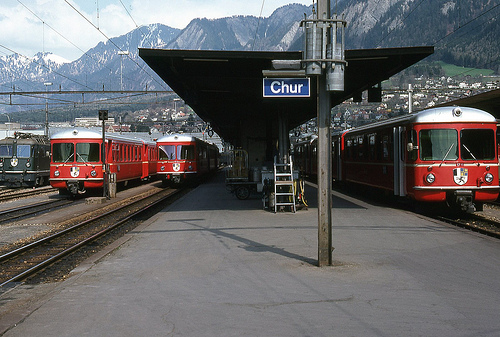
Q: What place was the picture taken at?
A: It was taken at the station.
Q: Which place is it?
A: It is a station.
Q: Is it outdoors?
A: Yes, it is outdoors.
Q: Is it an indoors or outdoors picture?
A: It is outdoors.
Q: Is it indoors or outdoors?
A: It is outdoors.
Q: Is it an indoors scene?
A: No, it is outdoors.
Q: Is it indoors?
A: No, it is outdoors.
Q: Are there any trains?
A: Yes, there is a train.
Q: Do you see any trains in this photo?
A: Yes, there is a train.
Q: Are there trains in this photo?
A: Yes, there is a train.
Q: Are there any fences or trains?
A: Yes, there is a train.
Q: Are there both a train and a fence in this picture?
A: No, there is a train but no fences.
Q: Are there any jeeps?
A: No, there are no jeeps.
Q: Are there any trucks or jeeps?
A: No, there are no jeeps or trucks.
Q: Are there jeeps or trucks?
A: No, there are no jeeps or trucks.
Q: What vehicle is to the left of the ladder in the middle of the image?
A: The vehicle is a train.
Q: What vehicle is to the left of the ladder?
A: The vehicle is a train.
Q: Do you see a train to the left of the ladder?
A: Yes, there is a train to the left of the ladder.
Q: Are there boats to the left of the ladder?
A: No, there is a train to the left of the ladder.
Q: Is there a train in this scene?
A: Yes, there are trains.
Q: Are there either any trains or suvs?
A: Yes, there are trains.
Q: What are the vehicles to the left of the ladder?
A: The vehicles are trains.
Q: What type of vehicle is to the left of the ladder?
A: The vehicles are trains.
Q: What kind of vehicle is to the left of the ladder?
A: The vehicles are trains.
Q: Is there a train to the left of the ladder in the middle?
A: Yes, there are trains to the left of the ladder.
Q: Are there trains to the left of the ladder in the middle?
A: Yes, there are trains to the left of the ladder.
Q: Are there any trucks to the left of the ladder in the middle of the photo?
A: No, there are trains to the left of the ladder.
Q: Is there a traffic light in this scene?
A: No, there are no traffic lights.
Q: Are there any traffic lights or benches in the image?
A: No, there are no traffic lights or benches.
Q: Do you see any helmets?
A: No, there are no helmets.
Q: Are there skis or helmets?
A: No, there are no helmets or skis.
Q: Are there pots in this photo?
A: No, there are no pots.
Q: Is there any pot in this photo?
A: No, there are no pots.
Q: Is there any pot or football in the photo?
A: No, there are no pots or footballs.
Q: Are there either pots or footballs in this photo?
A: No, there are no pots or footballs.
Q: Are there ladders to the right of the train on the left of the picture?
A: Yes, there is a ladder to the right of the train.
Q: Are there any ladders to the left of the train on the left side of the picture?
A: No, the ladder is to the right of the train.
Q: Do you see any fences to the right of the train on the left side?
A: No, there is a ladder to the right of the train.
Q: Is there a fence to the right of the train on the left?
A: No, there is a ladder to the right of the train.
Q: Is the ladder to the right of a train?
A: Yes, the ladder is to the right of a train.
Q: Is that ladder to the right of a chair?
A: No, the ladder is to the right of a train.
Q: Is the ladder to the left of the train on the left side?
A: No, the ladder is to the right of the train.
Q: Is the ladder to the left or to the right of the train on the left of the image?
A: The ladder is to the right of the train.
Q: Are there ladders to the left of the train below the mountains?
A: Yes, there is a ladder to the left of the train.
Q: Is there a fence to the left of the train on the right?
A: No, there is a ladder to the left of the train.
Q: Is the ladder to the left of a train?
A: Yes, the ladder is to the left of a train.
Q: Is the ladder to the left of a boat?
A: No, the ladder is to the left of a train.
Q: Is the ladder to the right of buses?
A: No, the ladder is to the right of the trains.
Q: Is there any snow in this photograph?
A: Yes, there is snow.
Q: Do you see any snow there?
A: Yes, there is snow.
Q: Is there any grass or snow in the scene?
A: Yes, there is snow.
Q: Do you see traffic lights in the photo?
A: No, there are no traffic lights.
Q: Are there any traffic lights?
A: No, there are no traffic lights.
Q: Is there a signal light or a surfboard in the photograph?
A: No, there are no traffic lights or surfboards.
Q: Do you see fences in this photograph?
A: No, there are no fences.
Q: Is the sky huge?
A: Yes, the sky is huge.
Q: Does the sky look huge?
A: Yes, the sky is huge.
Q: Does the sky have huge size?
A: Yes, the sky is huge.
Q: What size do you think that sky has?
A: The sky has huge size.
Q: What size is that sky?
A: The sky is huge.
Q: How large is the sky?
A: The sky is huge.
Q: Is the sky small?
A: No, the sky is huge.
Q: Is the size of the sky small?
A: No, the sky is huge.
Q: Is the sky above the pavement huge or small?
A: The sky is huge.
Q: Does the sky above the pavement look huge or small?
A: The sky is huge.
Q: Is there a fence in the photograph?
A: No, there are no fences.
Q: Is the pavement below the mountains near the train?
A: Yes, the pavement is below the mountains.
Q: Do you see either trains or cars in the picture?
A: Yes, there is a train.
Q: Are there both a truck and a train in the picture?
A: No, there is a train but no trucks.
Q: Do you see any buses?
A: No, there are no buses.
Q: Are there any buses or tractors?
A: No, there are no buses or tractors.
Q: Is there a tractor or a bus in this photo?
A: No, there are no buses or tractors.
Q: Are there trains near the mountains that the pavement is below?
A: Yes, there is a train near the mountains.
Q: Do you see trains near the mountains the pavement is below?
A: Yes, there is a train near the mountains.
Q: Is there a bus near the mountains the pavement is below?
A: No, there is a train near the mountains.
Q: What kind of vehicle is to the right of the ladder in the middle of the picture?
A: The vehicle is a train.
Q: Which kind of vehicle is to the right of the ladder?
A: The vehicle is a train.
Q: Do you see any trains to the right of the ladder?
A: Yes, there is a train to the right of the ladder.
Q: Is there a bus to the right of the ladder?
A: No, there is a train to the right of the ladder.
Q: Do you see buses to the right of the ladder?
A: No, there is a train to the right of the ladder.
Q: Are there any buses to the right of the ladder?
A: No, there is a train to the right of the ladder.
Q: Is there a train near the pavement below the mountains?
A: Yes, there is a train near the pavement.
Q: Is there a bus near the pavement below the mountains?
A: No, there is a train near the pavement.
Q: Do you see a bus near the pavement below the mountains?
A: No, there is a train near the pavement.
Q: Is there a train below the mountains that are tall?
A: Yes, there is a train below the mountains.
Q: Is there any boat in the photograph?
A: No, there are no boats.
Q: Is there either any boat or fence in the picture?
A: No, there are no boats or fences.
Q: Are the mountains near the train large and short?
A: No, the mountains are large but tall.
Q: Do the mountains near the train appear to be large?
A: Yes, the mountains are large.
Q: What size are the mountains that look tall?
A: The mountains are large.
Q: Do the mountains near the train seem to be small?
A: No, the mountains are large.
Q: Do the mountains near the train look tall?
A: Yes, the mountains are tall.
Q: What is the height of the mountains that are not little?
A: The mountains are tall.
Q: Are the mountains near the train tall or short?
A: The mountains are tall.